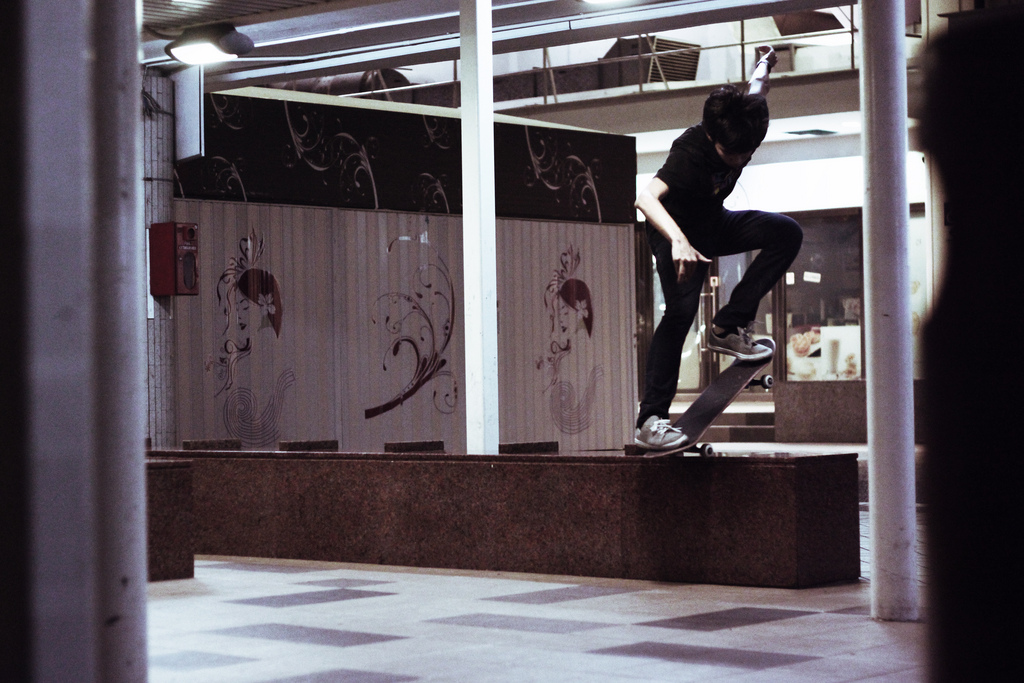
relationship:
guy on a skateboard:
[633, 44, 802, 450] [637, 335, 789, 474]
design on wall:
[203, 228, 294, 449] [175, 184, 348, 431]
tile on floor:
[387, 582, 543, 676] [261, 521, 726, 666]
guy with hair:
[633, 44, 802, 450] [706, 83, 767, 151]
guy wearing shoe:
[633, 44, 802, 450] [626, 404, 709, 457]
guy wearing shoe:
[633, 44, 802, 450] [706, 314, 782, 364]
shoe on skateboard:
[633, 415, 687, 449] [643, 320, 782, 474]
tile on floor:
[654, 586, 827, 643] [447, 554, 865, 676]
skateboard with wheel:
[643, 338, 777, 458] [659, 430, 722, 465]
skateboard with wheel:
[643, 338, 777, 458] [743, 370, 778, 392]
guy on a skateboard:
[633, 44, 802, 450] [622, 324, 787, 499]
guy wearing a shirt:
[670, 68, 787, 196] [661, 124, 748, 241]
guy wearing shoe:
[633, 44, 802, 450] [633, 415, 687, 449]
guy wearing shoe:
[633, 44, 802, 450] [707, 320, 773, 360]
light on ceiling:
[162, 22, 255, 65] [93, 1, 709, 129]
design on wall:
[203, 240, 299, 409] [170, 190, 354, 465]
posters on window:
[790, 318, 868, 383] [785, 220, 868, 387]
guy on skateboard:
[633, 44, 802, 450] [619, 437, 715, 459]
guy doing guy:
[633, 44, 802, 450] [633, 44, 802, 450]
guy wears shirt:
[633, 44, 802, 450] [647, 80, 781, 227]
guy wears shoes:
[633, 44, 802, 450] [641, 326, 748, 461]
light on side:
[153, 18, 255, 70] [144, 0, 272, 577]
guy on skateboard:
[633, 44, 802, 450] [693, 339, 767, 452]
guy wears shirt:
[633, 44, 802, 450] [651, 87, 775, 232]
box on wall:
[144, 205, 209, 316] [152, 99, 300, 441]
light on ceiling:
[162, 22, 255, 65] [142, 4, 464, 84]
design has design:
[203, 228, 294, 449] [203, 228, 294, 449]